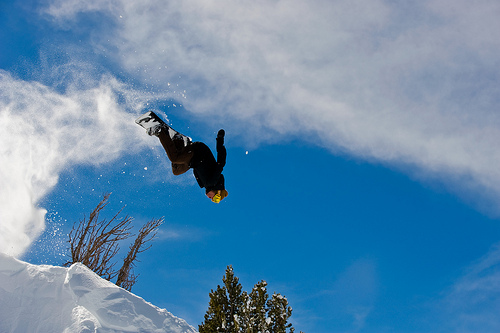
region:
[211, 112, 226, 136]
part of a glove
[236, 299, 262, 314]
part of a tree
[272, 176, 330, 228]
part of the sky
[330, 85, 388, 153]
part of a cloud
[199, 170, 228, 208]
part of a google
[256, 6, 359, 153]
part of a smoke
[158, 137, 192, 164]
part of a trouser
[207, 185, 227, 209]
Person wearing yellow hat.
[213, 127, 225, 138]
Person wearing dark mittens.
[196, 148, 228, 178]
Person wearing black coat.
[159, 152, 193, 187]
Person wearing brown pants.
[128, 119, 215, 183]
Person doing trick on snow board.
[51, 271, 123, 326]
Ground is covered in snow.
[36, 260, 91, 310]
Snow on ground is white.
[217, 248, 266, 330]
Green leaves on tree.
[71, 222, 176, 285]
Bare tree branches on near tree.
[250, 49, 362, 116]
White clouds in the sky.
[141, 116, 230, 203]
Snowboarder in the air.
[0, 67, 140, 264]
Large trail of white snow coming off the snowboarder.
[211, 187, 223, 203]
Yellow goggles on the face of a snowboarder in the air.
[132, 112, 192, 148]
Dark snowboard with snow on it.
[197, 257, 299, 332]
Top of a pointy green tree with snow on it.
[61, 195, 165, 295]
Tall leafless branches on the top of a hill.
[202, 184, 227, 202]
Head of a person upside down in the air.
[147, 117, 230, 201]
Person in the air with yellow goggles.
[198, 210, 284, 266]
Blue sky between the leafy tree and the snowboarder.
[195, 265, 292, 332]
Top of a green leafy tree.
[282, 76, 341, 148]
part of a smoke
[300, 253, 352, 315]
part of the sky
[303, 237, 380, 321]
part of the sky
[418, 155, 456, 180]
edge of a snow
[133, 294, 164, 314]
edge of a snow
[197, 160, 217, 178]
part of a jacket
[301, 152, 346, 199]
part of the sky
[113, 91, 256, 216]
a snowboarder in the air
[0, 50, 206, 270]
some snow kicked up in the air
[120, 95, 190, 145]
a black and white snowboard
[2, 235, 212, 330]
a white snow hill on the lower left corner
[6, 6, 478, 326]
a blue sky with clouds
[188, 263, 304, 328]
a green tree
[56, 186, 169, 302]
a leafless tree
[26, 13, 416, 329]
a scene outside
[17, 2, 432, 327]
a scene happening during the day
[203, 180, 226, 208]
a golden goggles